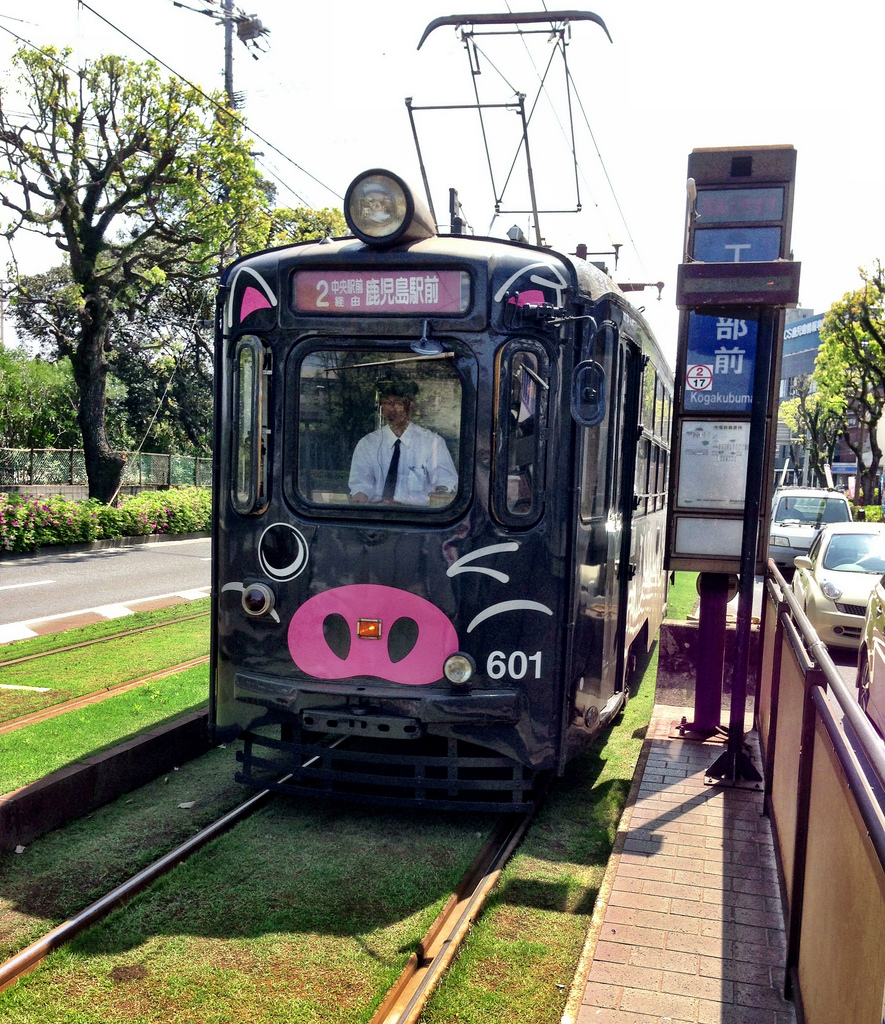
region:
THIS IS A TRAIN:
[160, 168, 694, 834]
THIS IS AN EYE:
[249, 510, 313, 597]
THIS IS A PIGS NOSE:
[278, 573, 465, 707]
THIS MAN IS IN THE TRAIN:
[326, 361, 467, 541]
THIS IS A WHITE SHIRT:
[337, 413, 478, 534]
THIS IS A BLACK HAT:
[370, 369, 421, 406]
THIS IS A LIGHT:
[417, 648, 513, 690]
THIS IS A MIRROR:
[542, 314, 606, 470]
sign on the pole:
[680, 521, 739, 555]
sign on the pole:
[681, 421, 751, 510]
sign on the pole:
[690, 234, 774, 263]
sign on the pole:
[690, 192, 781, 227]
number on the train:
[484, 645, 505, 677]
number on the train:
[520, 638, 552, 689]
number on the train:
[312, 282, 330, 311]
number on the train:
[345, 283, 365, 307]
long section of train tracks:
[87, 805, 516, 1007]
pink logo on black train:
[272, 557, 474, 693]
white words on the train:
[486, 640, 554, 681]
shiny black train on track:
[166, 114, 686, 784]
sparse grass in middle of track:
[230, 877, 341, 975]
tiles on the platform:
[650, 854, 744, 969]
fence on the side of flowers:
[24, 416, 171, 522]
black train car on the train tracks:
[215, 167, 677, 813]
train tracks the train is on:
[9, 749, 575, 1020]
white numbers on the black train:
[483, 637, 542, 685]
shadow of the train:
[3, 701, 516, 1020]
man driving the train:
[340, 370, 458, 505]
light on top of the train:
[340, 162, 419, 249]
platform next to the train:
[542, 681, 798, 1021]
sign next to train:
[675, 131, 784, 574]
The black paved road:
[4, 550, 213, 614]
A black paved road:
[6, 551, 232, 620]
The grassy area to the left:
[3, 604, 249, 802]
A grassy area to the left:
[1, 594, 237, 763]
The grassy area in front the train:
[14, 747, 496, 1020]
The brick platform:
[577, 683, 798, 1019]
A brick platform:
[569, 680, 804, 1015]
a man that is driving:
[335, 377, 452, 508]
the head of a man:
[369, 371, 424, 438]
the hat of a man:
[372, 378, 417, 399]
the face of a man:
[372, 395, 406, 425]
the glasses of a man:
[380, 396, 397, 418]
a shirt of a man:
[331, 415, 458, 506]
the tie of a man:
[376, 433, 420, 505]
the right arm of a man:
[421, 433, 463, 506]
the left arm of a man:
[342, 437, 376, 506]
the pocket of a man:
[388, 459, 436, 496]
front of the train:
[108, 235, 647, 822]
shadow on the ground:
[238, 882, 403, 980]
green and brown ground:
[180, 917, 357, 1021]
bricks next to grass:
[577, 810, 765, 989]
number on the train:
[453, 604, 580, 710]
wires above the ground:
[407, 28, 625, 137]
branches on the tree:
[57, 178, 191, 314]